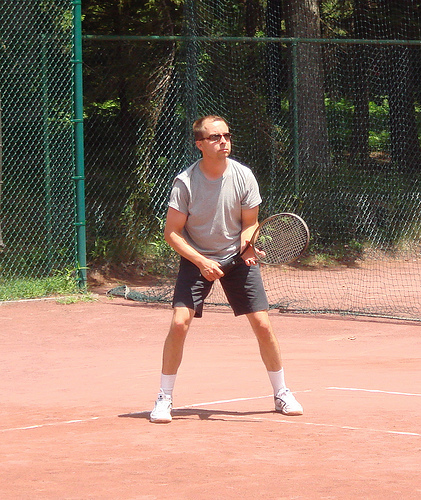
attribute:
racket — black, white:
[226, 205, 337, 269]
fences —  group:
[309, 42, 390, 195]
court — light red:
[3, 276, 417, 496]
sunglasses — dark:
[209, 131, 231, 146]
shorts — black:
[171, 253, 272, 317]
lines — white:
[0, 382, 411, 451]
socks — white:
[250, 356, 304, 402]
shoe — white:
[147, 391, 312, 425]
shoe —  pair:
[273, 391, 303, 414]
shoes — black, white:
[139, 386, 306, 426]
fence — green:
[10, 16, 123, 303]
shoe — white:
[147, 389, 179, 426]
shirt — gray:
[159, 158, 265, 272]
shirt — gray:
[161, 156, 268, 266]